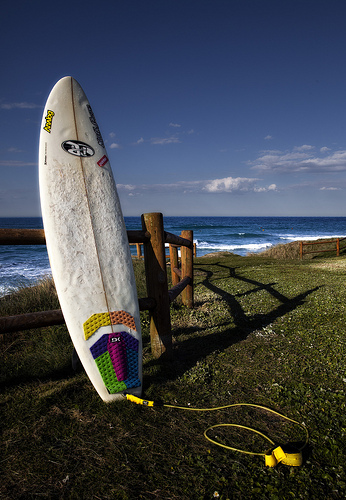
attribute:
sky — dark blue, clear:
[1, 1, 344, 215]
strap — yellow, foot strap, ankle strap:
[125, 390, 311, 467]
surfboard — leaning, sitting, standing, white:
[39, 74, 144, 404]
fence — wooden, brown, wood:
[5, 211, 196, 359]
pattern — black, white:
[59, 138, 96, 158]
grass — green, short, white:
[1, 256, 342, 495]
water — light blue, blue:
[5, 215, 345, 290]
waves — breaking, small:
[1, 215, 346, 297]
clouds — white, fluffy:
[3, 101, 345, 198]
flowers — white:
[59, 277, 345, 500]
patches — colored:
[84, 310, 142, 396]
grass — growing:
[1, 258, 180, 416]